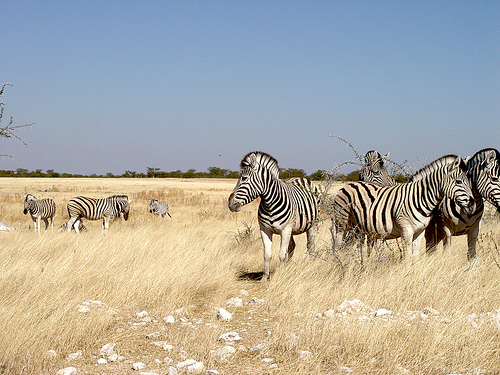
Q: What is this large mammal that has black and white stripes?
A: Zebra.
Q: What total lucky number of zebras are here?
A: Seven.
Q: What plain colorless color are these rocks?
A: White.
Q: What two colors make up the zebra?
A: Black and white.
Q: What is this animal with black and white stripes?
A: Zebra.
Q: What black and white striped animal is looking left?
A: Zebra.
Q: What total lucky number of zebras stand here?
A: Seven.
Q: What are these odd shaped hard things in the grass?
A: Rocks.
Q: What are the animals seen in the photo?
A: Zebras.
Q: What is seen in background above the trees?
A: Sky.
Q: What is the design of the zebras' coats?
A: Striped.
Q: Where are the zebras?
A: Field.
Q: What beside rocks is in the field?
A: Dried grass.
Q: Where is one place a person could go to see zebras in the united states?
A: Zoo.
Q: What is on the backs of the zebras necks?
A: Manes.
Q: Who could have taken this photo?
A: Wildlife photographer.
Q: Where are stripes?
A: On the zebra.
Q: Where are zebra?
A: On a grassy field.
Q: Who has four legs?
A: One zebra.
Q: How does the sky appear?
A: Clear and blue.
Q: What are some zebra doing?
A: Grazing.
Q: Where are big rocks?
A: On the field.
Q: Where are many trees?
A: In the far distance.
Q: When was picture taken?
A: In day time.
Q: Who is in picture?
A: No one.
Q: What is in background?
A: Trees.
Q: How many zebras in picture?
A: Six.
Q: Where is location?
A: Out in the wilds.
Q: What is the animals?
A: Zebras.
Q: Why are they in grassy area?
A: Grazing.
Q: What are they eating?
A: Grass.